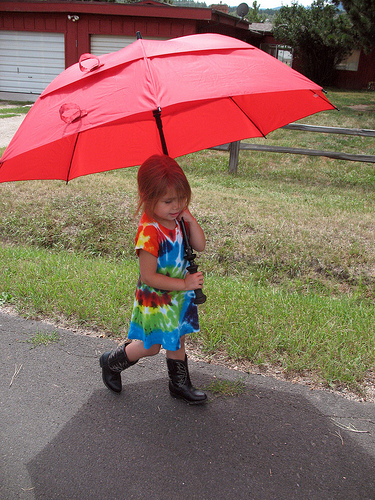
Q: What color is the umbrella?
A: Red.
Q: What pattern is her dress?
A: Rainbow.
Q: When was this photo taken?
A: During the day.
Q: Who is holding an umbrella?
A: The girl.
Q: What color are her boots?
A: Black.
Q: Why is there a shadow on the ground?
A: The umbrella.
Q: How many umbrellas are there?
A: 1.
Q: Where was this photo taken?
A: On a street.